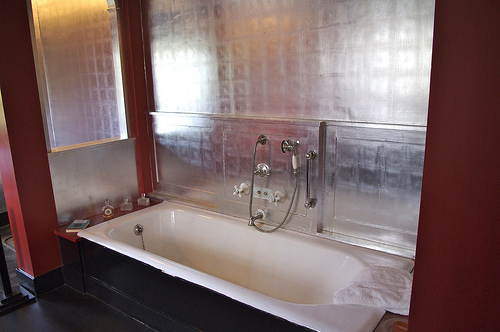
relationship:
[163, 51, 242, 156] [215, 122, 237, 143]
glass wearing frosted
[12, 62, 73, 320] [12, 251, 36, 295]
walls are red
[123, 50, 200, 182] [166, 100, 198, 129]
light refelcting on wall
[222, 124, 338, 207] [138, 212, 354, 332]
knobs are on tub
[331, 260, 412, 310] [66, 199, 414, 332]
towel on bathtub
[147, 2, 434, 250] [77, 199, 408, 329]
wall behind bathtub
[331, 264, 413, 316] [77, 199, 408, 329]
towel on bathtub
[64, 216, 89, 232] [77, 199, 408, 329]
book beside bathtub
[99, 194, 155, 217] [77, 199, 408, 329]
bottles beside bathtub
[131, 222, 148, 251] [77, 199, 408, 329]
drain for bathtub